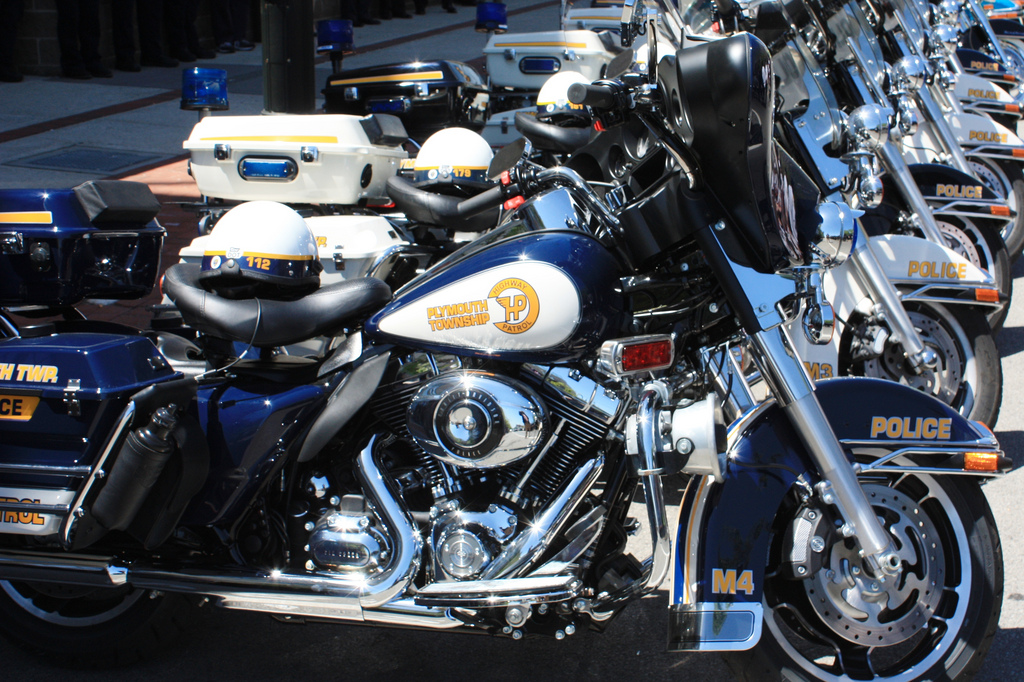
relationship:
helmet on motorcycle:
[190, 193, 323, 292] [3, 27, 1018, 679]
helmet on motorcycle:
[404, 123, 496, 187] [155, 68, 1015, 424]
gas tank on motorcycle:
[373, 228, 609, 366] [3, 27, 1018, 679]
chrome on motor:
[272, 550, 507, 667] [373, 392, 627, 631]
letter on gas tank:
[512, 288, 528, 321] [365, 215, 625, 380]